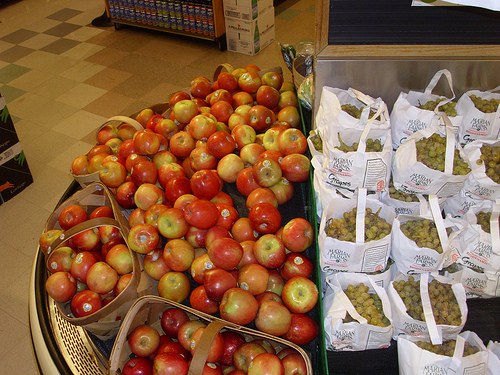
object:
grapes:
[392, 276, 462, 326]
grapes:
[413, 338, 479, 357]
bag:
[388, 271, 469, 345]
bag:
[318, 186, 396, 273]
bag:
[391, 193, 464, 276]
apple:
[86, 261, 118, 293]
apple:
[45, 271, 77, 303]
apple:
[128, 324, 160, 357]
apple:
[178, 320, 206, 351]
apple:
[105, 244, 132, 275]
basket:
[44, 180, 152, 341]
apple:
[161, 308, 191, 340]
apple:
[189, 326, 224, 363]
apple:
[246, 352, 284, 374]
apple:
[153, 352, 188, 374]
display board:
[325, 0, 499, 48]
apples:
[280, 252, 312, 280]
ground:
[24, 65, 101, 131]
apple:
[70, 290, 102, 318]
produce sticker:
[83, 302, 92, 312]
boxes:
[221, 0, 277, 56]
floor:
[1, 2, 316, 374]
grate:
[47, 296, 105, 375]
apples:
[97, 123, 118, 145]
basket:
[69, 101, 173, 188]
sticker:
[294, 256, 304, 264]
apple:
[238, 264, 270, 295]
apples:
[155, 119, 180, 141]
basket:
[108, 294, 314, 374]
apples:
[123, 357, 153, 375]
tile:
[22, 98, 79, 129]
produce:
[127, 64, 315, 345]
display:
[32, 61, 498, 372]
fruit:
[252, 157, 282, 187]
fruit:
[233, 91, 254, 109]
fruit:
[253, 233, 286, 269]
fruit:
[128, 223, 159, 254]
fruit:
[134, 131, 161, 155]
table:
[27, 175, 117, 372]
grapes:
[415, 133, 472, 175]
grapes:
[400, 219, 452, 253]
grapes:
[324, 207, 391, 243]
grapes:
[334, 132, 385, 152]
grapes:
[415, 98, 457, 117]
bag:
[447, 199, 500, 298]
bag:
[396, 329, 499, 374]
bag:
[315, 85, 391, 146]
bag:
[391, 68, 464, 150]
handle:
[44, 217, 121, 273]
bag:
[322, 272, 394, 352]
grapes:
[342, 282, 391, 327]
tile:
[82, 67, 134, 91]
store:
[0, 0, 490, 368]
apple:
[252, 234, 286, 269]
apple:
[232, 342, 268, 373]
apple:
[157, 272, 190, 304]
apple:
[144, 204, 170, 230]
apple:
[158, 162, 186, 189]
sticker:
[240, 282, 249, 291]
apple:
[202, 268, 237, 301]